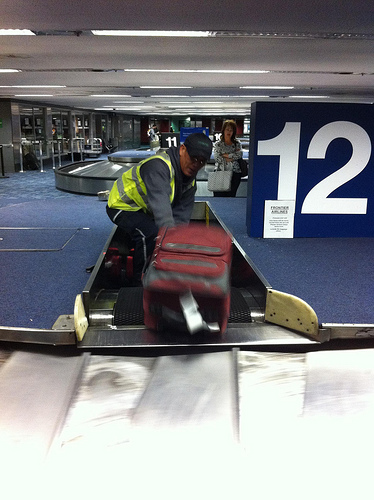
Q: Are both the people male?
A: No, they are both male and female.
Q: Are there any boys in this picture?
A: No, there are no boys.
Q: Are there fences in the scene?
A: No, there are no fences.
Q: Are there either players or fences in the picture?
A: No, there are no fences or players.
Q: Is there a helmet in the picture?
A: No, there are no helmets.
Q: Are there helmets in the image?
A: No, there are no helmets.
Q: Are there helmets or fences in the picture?
A: No, there are no helmets or fences.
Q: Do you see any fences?
A: No, there are no fences.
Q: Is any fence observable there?
A: No, there are no fences.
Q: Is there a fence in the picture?
A: No, there are no fences.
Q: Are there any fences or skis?
A: No, there are no fences or skis.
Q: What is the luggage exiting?
A: The luggage is exiting the belt.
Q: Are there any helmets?
A: No, there are no helmets.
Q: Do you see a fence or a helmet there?
A: No, there are no helmets or fences.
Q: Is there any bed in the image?
A: No, there are no beds.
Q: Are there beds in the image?
A: No, there are no beds.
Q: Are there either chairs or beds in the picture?
A: No, there are no beds or chairs.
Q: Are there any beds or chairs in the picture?
A: No, there are no beds or chairs.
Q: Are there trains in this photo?
A: No, there are no trains.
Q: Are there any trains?
A: No, there are no trains.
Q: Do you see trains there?
A: No, there are no trains.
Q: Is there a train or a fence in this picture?
A: No, there are no trains or fences.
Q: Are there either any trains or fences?
A: No, there are no trains or fences.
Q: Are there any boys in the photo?
A: No, there are no boys.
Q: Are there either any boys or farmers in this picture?
A: No, there are no boys or farmers.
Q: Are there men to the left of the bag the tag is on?
A: Yes, there is a man to the left of the bag.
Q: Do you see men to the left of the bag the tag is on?
A: Yes, there is a man to the left of the bag.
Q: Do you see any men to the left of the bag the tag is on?
A: Yes, there is a man to the left of the bag.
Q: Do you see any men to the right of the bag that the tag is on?
A: No, the man is to the left of the bag.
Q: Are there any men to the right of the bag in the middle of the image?
A: No, the man is to the left of the bag.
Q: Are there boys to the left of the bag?
A: No, there is a man to the left of the bag.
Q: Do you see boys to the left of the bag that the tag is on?
A: No, there is a man to the left of the bag.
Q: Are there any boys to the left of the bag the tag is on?
A: No, there is a man to the left of the bag.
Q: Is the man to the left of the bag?
A: Yes, the man is to the left of the bag.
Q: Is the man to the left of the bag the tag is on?
A: Yes, the man is to the left of the bag.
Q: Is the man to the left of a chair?
A: No, the man is to the left of the bag.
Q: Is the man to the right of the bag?
A: No, the man is to the left of the bag.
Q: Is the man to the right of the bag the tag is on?
A: No, the man is to the left of the bag.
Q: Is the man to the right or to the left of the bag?
A: The man is to the left of the bag.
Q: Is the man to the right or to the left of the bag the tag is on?
A: The man is to the left of the bag.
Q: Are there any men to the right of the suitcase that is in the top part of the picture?
A: Yes, there is a man to the right of the suitcase.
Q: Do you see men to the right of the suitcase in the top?
A: Yes, there is a man to the right of the suitcase.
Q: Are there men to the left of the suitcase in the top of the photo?
A: No, the man is to the right of the suitcase.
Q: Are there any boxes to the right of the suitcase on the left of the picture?
A: No, there is a man to the right of the suitcase.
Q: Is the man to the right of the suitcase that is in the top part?
A: Yes, the man is to the right of the suitcase.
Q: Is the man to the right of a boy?
A: No, the man is to the right of the suitcase.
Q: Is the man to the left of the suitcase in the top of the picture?
A: No, the man is to the right of the suitcase.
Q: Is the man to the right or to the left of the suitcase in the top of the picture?
A: The man is to the right of the suitcase.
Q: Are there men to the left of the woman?
A: Yes, there is a man to the left of the woman.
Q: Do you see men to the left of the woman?
A: Yes, there is a man to the left of the woman.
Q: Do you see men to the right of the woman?
A: No, the man is to the left of the woman.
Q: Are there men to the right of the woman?
A: No, the man is to the left of the woman.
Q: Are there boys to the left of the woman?
A: No, there is a man to the left of the woman.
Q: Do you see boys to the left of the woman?
A: No, there is a man to the left of the woman.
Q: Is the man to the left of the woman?
A: Yes, the man is to the left of the woman.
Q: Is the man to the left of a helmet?
A: No, the man is to the left of the woman.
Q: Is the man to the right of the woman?
A: No, the man is to the left of the woman.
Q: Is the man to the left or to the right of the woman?
A: The man is to the left of the woman.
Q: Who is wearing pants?
A: The man is wearing pants.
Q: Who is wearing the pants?
A: The man is wearing pants.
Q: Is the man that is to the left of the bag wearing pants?
A: Yes, the man is wearing pants.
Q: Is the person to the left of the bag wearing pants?
A: Yes, the man is wearing pants.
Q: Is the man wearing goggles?
A: No, the man is wearing pants.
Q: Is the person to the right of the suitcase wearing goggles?
A: No, the man is wearing pants.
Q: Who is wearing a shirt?
A: The man is wearing a shirt.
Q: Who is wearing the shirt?
A: The man is wearing a shirt.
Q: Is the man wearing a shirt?
A: Yes, the man is wearing a shirt.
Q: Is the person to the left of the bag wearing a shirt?
A: Yes, the man is wearing a shirt.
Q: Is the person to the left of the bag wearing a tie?
A: No, the man is wearing a shirt.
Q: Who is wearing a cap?
A: The man is wearing a cap.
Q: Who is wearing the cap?
A: The man is wearing a cap.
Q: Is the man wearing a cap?
A: Yes, the man is wearing a cap.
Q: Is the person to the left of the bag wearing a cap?
A: Yes, the man is wearing a cap.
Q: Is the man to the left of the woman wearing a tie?
A: No, the man is wearing a cap.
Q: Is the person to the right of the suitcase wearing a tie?
A: No, the man is wearing a cap.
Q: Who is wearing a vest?
A: The man is wearing a vest.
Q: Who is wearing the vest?
A: The man is wearing a vest.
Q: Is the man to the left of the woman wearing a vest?
A: Yes, the man is wearing a vest.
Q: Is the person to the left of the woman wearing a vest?
A: Yes, the man is wearing a vest.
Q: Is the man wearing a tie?
A: No, the man is wearing a vest.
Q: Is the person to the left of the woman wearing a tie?
A: No, the man is wearing a vest.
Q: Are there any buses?
A: No, there are no buses.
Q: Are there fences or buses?
A: No, there are no buses or fences.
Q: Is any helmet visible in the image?
A: No, there are no helmets.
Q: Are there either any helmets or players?
A: No, there are no helmets or players.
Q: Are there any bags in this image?
A: Yes, there is a bag.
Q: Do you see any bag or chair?
A: Yes, there is a bag.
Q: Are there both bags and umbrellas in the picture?
A: No, there is a bag but no umbrellas.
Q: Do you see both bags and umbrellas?
A: No, there is a bag but no umbrellas.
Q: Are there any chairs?
A: No, there are no chairs.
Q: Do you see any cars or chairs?
A: No, there are no chairs or cars.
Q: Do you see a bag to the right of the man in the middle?
A: Yes, there is a bag to the right of the man.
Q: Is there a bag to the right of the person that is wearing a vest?
A: Yes, there is a bag to the right of the man.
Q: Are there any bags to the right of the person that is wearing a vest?
A: Yes, there is a bag to the right of the man.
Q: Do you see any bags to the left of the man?
A: No, the bag is to the right of the man.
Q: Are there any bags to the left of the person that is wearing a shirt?
A: No, the bag is to the right of the man.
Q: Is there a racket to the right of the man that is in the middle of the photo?
A: No, there is a bag to the right of the man.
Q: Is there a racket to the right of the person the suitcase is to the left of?
A: No, there is a bag to the right of the man.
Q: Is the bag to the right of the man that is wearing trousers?
A: Yes, the bag is to the right of the man.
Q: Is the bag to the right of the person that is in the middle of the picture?
A: Yes, the bag is to the right of the man.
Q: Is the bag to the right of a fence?
A: No, the bag is to the right of the man.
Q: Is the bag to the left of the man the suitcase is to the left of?
A: No, the bag is to the right of the man.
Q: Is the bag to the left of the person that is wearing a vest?
A: No, the bag is to the right of the man.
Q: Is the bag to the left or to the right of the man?
A: The bag is to the right of the man.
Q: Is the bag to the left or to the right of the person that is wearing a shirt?
A: The bag is to the right of the man.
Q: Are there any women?
A: Yes, there is a woman.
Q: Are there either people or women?
A: Yes, there is a woman.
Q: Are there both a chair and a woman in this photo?
A: No, there is a woman but no chairs.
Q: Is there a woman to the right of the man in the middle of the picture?
A: Yes, there is a woman to the right of the man.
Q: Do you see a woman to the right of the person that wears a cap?
A: Yes, there is a woman to the right of the man.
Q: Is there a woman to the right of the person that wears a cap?
A: Yes, there is a woman to the right of the man.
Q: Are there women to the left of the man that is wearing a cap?
A: No, the woman is to the right of the man.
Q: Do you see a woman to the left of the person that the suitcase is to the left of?
A: No, the woman is to the right of the man.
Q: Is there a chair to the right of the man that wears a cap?
A: No, there is a woman to the right of the man.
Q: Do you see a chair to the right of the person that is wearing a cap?
A: No, there is a woman to the right of the man.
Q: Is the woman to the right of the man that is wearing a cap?
A: Yes, the woman is to the right of the man.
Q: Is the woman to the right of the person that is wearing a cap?
A: Yes, the woman is to the right of the man.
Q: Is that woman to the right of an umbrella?
A: No, the woman is to the right of the man.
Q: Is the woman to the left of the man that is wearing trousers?
A: No, the woman is to the right of the man.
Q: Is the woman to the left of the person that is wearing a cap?
A: No, the woman is to the right of the man.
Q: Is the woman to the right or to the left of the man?
A: The woman is to the right of the man.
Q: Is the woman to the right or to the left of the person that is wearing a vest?
A: The woman is to the right of the man.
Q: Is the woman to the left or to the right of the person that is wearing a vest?
A: The woman is to the right of the man.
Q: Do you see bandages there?
A: No, there are no bandages.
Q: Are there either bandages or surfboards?
A: No, there are no bandages or surfboards.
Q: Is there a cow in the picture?
A: No, there are no cows.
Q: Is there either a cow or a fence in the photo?
A: No, there are no cows or fences.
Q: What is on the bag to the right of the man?
A: The tag is on the bag.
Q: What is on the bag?
A: The tag is on the bag.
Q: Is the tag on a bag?
A: Yes, the tag is on a bag.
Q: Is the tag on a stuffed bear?
A: No, the tag is on a bag.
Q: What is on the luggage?
A: The tag is on the luggage.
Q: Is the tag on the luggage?
A: Yes, the tag is on the luggage.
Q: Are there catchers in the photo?
A: No, there are no catchers.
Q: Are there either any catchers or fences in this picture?
A: No, there are no catchers or fences.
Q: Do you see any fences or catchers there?
A: No, there are no catchers or fences.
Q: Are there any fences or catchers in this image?
A: No, there are no catchers or fences.